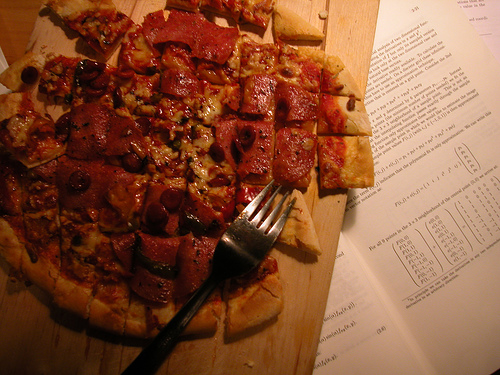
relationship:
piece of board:
[42, 1, 133, 58] [0, 1, 381, 374]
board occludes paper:
[0, 1, 381, 374] [312, 2, 499, 374]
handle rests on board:
[119, 278, 222, 374] [0, 1, 381, 374]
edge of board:
[316, 54, 376, 192] [0, 1, 381, 374]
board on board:
[0, 1, 381, 374] [0, 1, 381, 374]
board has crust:
[0, 1, 381, 374] [275, 14, 378, 187]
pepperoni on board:
[65, 103, 149, 161] [0, 1, 381, 374]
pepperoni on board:
[215, 116, 274, 172] [0, 1, 381, 374]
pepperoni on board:
[155, 8, 240, 65] [0, 1, 381, 374]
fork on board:
[117, 180, 298, 374] [0, 1, 381, 374]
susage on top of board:
[118, 92, 159, 119] [0, 1, 381, 374]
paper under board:
[312, 2, 499, 374] [0, 1, 381, 374]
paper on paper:
[312, 0, 500, 375] [312, 2, 499, 374]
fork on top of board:
[117, 180, 298, 374] [0, 1, 381, 374]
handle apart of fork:
[119, 278, 222, 374] [117, 180, 298, 374]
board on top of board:
[0, 1, 381, 374] [0, 1, 381, 374]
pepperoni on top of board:
[65, 103, 149, 161] [0, 1, 381, 374]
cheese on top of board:
[11, 0, 304, 297] [0, 1, 381, 374]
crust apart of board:
[275, 14, 378, 187] [0, 1, 381, 374]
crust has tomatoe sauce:
[275, 14, 378, 187] [319, 66, 345, 191]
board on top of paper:
[0, 1, 381, 374] [312, 2, 499, 374]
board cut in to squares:
[0, 1, 381, 374] [318, 135, 376, 190]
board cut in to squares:
[0, 1, 381, 374] [70, 57, 118, 109]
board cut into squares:
[0, 1, 381, 374] [318, 135, 376, 190]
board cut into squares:
[0, 1, 381, 374] [70, 57, 118, 109]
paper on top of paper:
[312, 0, 500, 375] [312, 2, 499, 374]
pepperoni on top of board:
[215, 116, 274, 172] [0, 1, 381, 374]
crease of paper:
[342, 228, 439, 374] [312, 2, 499, 374]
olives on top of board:
[69, 170, 93, 192] [0, 1, 381, 374]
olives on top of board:
[240, 124, 257, 145] [0, 1, 381, 374]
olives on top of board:
[160, 188, 182, 211] [0, 1, 381, 374]